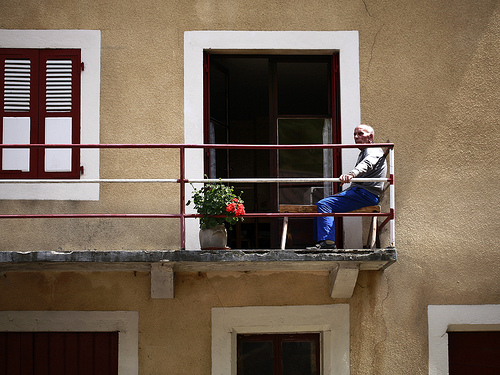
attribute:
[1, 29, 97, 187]
blinds — brown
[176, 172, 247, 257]
plant — green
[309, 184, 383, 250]
pants — blue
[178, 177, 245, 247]
plant — potted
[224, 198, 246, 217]
flowers — red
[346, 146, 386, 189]
shirt — white 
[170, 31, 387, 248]
doorway — white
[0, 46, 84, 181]
shutters — closed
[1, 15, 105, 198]
window — white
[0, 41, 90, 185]
table — red, white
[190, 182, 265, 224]
flower — red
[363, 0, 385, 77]
crack — hair line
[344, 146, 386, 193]
jacket — tan